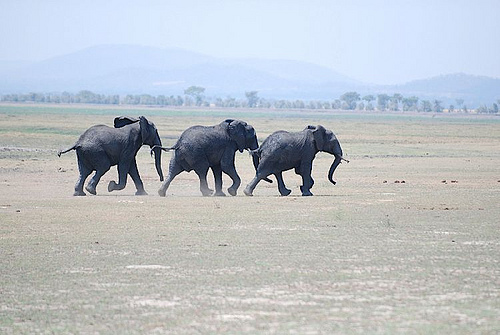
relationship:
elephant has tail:
[57, 114, 163, 199] [56, 146, 77, 154]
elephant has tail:
[151, 120, 272, 198] [151, 144, 177, 154]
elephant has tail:
[244, 125, 350, 199] [247, 148, 262, 154]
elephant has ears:
[57, 114, 163, 199] [113, 117, 151, 141]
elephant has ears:
[151, 120, 272, 198] [224, 119, 246, 151]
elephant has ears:
[244, 125, 350, 199] [308, 124, 327, 150]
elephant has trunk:
[57, 114, 163, 199] [151, 136, 164, 183]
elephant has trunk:
[151, 120, 272, 198] [250, 141, 272, 183]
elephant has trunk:
[244, 125, 350, 199] [328, 152, 340, 185]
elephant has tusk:
[244, 125, 350, 199] [337, 153, 350, 163]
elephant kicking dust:
[57, 114, 163, 196] [67, 182, 313, 199]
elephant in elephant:
[151, 120, 272, 198] [244, 125, 350, 196]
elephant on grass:
[57, 114, 163, 196] [1, 103, 499, 333]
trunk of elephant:
[151, 136, 164, 183] [57, 114, 163, 199]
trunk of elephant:
[250, 141, 272, 183] [151, 120, 272, 198]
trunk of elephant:
[328, 152, 340, 185] [244, 125, 350, 199]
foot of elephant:
[108, 182, 117, 193] [57, 114, 163, 199]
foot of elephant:
[135, 190, 148, 197] [57, 114, 163, 199]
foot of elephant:
[86, 185, 97, 195] [57, 114, 163, 199]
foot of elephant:
[73, 187, 85, 196] [57, 114, 163, 199]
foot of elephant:
[158, 185, 166, 196] [151, 120, 272, 198]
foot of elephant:
[200, 187, 212, 195] [151, 120, 272, 198]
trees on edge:
[1, 87, 498, 112] [2, 103, 499, 113]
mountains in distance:
[1, 48, 498, 102] [1, 1, 499, 129]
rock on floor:
[16, 209, 21, 215] [1, 103, 499, 333]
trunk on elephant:
[151, 136, 164, 183] [57, 114, 163, 199]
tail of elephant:
[56, 146, 77, 154] [57, 114, 163, 199]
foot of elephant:
[214, 189, 226, 197] [151, 120, 272, 198]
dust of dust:
[67, 182, 313, 199] [67, 182, 313, 199]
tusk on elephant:
[337, 153, 350, 163] [244, 125, 350, 199]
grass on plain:
[1, 103, 499, 333] [0, 103, 499, 334]